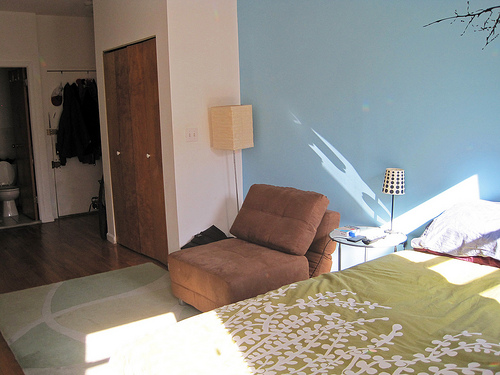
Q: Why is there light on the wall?
A: From the window.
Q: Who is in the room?
A: No one.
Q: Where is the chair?
A: Next to the bed.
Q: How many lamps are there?
A: 2.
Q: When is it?
A: Day time.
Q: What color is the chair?
A: Brown.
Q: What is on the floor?
A: Rug.